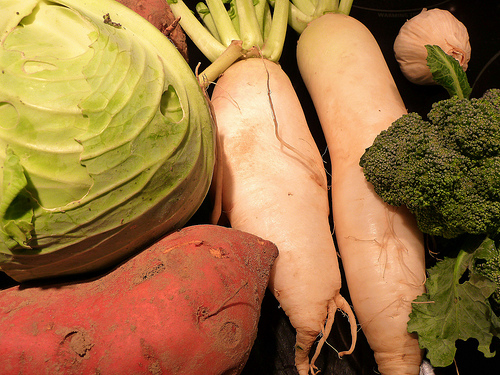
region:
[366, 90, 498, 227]
a piece of broccoli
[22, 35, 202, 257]
the cabbage is green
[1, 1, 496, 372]
pile of raw vegetables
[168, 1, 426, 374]
two carrots with stems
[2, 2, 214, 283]
head of green cabbage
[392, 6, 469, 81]
head of garlic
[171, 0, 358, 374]
carrot has two side roots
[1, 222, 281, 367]
sweet potato with some dirt on it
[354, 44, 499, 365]
head of broccoli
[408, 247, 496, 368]
broccoli leaf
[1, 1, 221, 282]
cabbage has one round bug hole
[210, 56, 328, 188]
carrot has a split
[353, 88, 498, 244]
A head of a piece of broccoli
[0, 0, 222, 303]
A head of lettuce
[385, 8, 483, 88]
A clove of garlic on the table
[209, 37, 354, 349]
A vegetable freshly pulled out of the ground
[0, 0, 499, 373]
A group of vegetables on the table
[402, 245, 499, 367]
A leaf of spinach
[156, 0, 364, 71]
Top most parts of the vegetables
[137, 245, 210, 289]
Some dirt residue still on the vegetable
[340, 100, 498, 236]
A dirty head of a broccoli piece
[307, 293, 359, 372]
Roots of the freshly picked vegetable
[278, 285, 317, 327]
part of a cassava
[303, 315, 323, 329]
part of a cassava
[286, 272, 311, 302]
part of a cassava